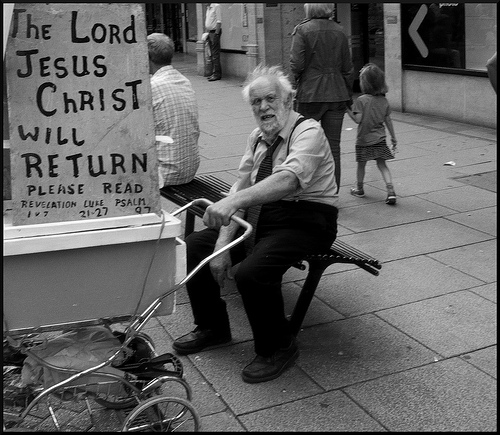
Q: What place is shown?
A: It is a sidewalk.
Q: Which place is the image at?
A: It is at the sidewalk.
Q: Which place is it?
A: It is a sidewalk.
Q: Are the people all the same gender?
A: No, they are both male and female.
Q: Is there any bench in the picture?
A: Yes, there is a bench.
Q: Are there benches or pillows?
A: Yes, there is a bench.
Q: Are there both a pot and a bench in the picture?
A: No, there is a bench but no pots.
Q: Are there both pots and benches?
A: No, there is a bench but no pots.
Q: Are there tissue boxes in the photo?
A: No, there are no tissue boxes.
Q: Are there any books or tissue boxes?
A: No, there are no tissue boxes or books.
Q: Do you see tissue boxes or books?
A: No, there are no tissue boxes or books.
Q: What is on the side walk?
A: The bench is on the side walk.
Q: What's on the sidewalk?
A: The bench is on the side walk.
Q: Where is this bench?
A: The bench is on the sidewalk.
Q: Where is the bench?
A: The bench is on the sidewalk.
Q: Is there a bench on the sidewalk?
A: Yes, there is a bench on the sidewalk.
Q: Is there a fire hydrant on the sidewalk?
A: No, there is a bench on the sidewalk.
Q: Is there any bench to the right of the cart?
A: Yes, there is a bench to the right of the cart.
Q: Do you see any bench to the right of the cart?
A: Yes, there is a bench to the right of the cart.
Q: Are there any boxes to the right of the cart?
A: No, there is a bench to the right of the cart.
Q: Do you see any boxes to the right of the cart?
A: No, there is a bench to the right of the cart.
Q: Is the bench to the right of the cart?
A: Yes, the bench is to the right of the cart.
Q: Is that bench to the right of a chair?
A: No, the bench is to the right of the cart.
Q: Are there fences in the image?
A: No, there are no fences.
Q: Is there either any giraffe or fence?
A: No, there are no fences or giraffes.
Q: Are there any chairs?
A: No, there are no chairs.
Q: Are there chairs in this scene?
A: No, there are no chairs.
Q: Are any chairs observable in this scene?
A: No, there are no chairs.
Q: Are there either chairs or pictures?
A: No, there are no chairs or pictures.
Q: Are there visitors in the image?
A: No, there are no visitors.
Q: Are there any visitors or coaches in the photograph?
A: No, there are no visitors or coaches.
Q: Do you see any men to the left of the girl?
A: Yes, there is a man to the left of the girl.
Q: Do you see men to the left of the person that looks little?
A: Yes, there is a man to the left of the girl.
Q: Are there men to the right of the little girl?
A: No, the man is to the left of the girl.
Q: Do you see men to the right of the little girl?
A: No, the man is to the left of the girl.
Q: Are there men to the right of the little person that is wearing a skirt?
A: No, the man is to the left of the girl.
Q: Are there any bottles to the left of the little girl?
A: No, there is a man to the left of the girl.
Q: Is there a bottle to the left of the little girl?
A: No, there is a man to the left of the girl.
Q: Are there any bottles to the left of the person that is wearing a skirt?
A: No, there is a man to the left of the girl.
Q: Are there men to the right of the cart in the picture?
A: Yes, there is a man to the right of the cart.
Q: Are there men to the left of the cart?
A: No, the man is to the right of the cart.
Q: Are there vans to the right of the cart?
A: No, there is a man to the right of the cart.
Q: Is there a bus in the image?
A: No, there are no buses.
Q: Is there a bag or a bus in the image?
A: No, there are no buses or bags.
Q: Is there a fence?
A: No, there are no fences.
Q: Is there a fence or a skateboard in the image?
A: No, there are no fences or skateboards.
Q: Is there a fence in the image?
A: No, there are no fences.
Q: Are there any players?
A: No, there are no players.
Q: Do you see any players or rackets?
A: No, there are no players or rackets.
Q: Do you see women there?
A: Yes, there is a woman.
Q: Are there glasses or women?
A: Yes, there is a woman.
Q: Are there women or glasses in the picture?
A: Yes, there is a woman.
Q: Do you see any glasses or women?
A: Yes, there is a woman.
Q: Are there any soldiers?
A: No, there are no soldiers.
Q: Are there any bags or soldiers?
A: No, there are no soldiers or bags.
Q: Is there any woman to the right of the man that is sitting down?
A: Yes, there is a woman to the right of the man.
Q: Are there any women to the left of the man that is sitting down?
A: No, the woman is to the right of the man.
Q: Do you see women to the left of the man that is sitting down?
A: No, the woman is to the right of the man.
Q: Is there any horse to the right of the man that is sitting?
A: No, there is a woman to the right of the man.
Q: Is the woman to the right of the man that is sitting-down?
A: Yes, the woman is to the right of the man.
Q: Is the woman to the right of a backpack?
A: No, the woman is to the right of the man.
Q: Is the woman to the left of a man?
A: No, the woman is to the right of a man.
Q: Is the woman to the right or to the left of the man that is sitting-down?
A: The woman is to the right of the man.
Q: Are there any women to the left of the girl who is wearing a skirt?
A: Yes, there is a woman to the left of the girl.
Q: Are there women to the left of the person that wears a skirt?
A: Yes, there is a woman to the left of the girl.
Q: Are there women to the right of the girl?
A: No, the woman is to the left of the girl.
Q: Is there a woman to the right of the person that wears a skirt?
A: No, the woman is to the left of the girl.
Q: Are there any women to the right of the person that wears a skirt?
A: No, the woman is to the left of the girl.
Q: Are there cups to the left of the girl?
A: No, there is a woman to the left of the girl.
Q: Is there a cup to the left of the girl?
A: No, there is a woman to the left of the girl.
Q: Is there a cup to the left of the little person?
A: No, there is a woman to the left of the girl.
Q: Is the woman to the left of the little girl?
A: Yes, the woman is to the left of the girl.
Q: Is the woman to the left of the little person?
A: Yes, the woman is to the left of the girl.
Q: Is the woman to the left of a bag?
A: No, the woman is to the left of the girl.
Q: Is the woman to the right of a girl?
A: No, the woman is to the left of a girl.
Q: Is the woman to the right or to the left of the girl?
A: The woman is to the left of the girl.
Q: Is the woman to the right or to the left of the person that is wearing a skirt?
A: The woman is to the left of the girl.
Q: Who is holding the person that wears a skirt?
A: The woman is holding the girl.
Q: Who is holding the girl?
A: The woman is holding the girl.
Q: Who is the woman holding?
A: The woman is holding the girl.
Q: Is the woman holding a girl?
A: Yes, the woman is holding a girl.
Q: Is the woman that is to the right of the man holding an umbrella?
A: No, the woman is holding a girl.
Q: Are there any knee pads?
A: No, there are no knee pads.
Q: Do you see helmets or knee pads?
A: No, there are no knee pads or helmets.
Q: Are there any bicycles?
A: No, there are no bicycles.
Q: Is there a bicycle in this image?
A: No, there are no bicycles.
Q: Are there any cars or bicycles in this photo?
A: No, there are no bicycles or cars.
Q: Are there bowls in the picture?
A: No, there are no bowls.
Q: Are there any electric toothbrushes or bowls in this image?
A: No, there are no bowls or electric toothbrushes.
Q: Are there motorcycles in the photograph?
A: No, there are no motorcycles.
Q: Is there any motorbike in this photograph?
A: No, there are no motorcycles.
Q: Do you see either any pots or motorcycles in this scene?
A: No, there are no motorcycles or pots.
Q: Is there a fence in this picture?
A: No, there are no fences.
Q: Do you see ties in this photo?
A: Yes, there is a tie.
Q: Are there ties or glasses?
A: Yes, there is a tie.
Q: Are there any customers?
A: No, there are no customers.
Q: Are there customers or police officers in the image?
A: No, there are no customers or police officers.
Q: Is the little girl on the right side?
A: Yes, the girl is on the right of the image.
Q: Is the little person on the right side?
A: Yes, the girl is on the right of the image.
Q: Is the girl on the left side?
A: No, the girl is on the right of the image.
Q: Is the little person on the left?
A: No, the girl is on the right of the image.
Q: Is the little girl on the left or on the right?
A: The girl is on the right of the image.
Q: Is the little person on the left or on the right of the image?
A: The girl is on the right of the image.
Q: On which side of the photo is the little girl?
A: The girl is on the right of the image.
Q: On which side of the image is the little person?
A: The girl is on the right of the image.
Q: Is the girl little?
A: Yes, the girl is little.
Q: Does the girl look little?
A: Yes, the girl is little.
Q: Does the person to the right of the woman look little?
A: Yes, the girl is little.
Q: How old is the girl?
A: The girl is little.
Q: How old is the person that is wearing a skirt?
A: The girl is little.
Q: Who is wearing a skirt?
A: The girl is wearing a skirt.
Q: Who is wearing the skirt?
A: The girl is wearing a skirt.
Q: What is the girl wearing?
A: The girl is wearing a skirt.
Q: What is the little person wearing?
A: The girl is wearing a skirt.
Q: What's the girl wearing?
A: The girl is wearing a skirt.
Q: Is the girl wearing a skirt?
A: Yes, the girl is wearing a skirt.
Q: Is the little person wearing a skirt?
A: Yes, the girl is wearing a skirt.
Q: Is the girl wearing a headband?
A: No, the girl is wearing a skirt.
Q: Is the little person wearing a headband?
A: No, the girl is wearing a skirt.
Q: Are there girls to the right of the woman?
A: Yes, there is a girl to the right of the woman.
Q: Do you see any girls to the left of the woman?
A: No, the girl is to the right of the woman.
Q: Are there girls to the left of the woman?
A: No, the girl is to the right of the woman.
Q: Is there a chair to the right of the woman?
A: No, there is a girl to the right of the woman.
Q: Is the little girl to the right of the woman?
A: Yes, the girl is to the right of the woman.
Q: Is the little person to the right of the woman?
A: Yes, the girl is to the right of the woman.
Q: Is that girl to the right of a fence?
A: No, the girl is to the right of the woman.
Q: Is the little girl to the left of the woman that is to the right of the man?
A: No, the girl is to the right of the woman.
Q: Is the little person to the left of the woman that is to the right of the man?
A: No, the girl is to the right of the woman.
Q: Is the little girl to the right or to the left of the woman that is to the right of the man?
A: The girl is to the right of the woman.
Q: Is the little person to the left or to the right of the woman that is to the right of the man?
A: The girl is to the right of the woman.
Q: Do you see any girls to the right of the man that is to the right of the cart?
A: Yes, there is a girl to the right of the man.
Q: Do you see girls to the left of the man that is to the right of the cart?
A: No, the girl is to the right of the man.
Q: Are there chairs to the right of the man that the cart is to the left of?
A: No, there is a girl to the right of the man.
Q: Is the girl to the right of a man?
A: Yes, the girl is to the right of a man.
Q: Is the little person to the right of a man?
A: Yes, the girl is to the right of a man.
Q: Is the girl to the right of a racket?
A: No, the girl is to the right of a man.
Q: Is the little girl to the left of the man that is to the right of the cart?
A: No, the girl is to the right of the man.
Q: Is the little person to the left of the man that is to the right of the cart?
A: No, the girl is to the right of the man.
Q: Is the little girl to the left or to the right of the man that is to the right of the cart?
A: The girl is to the right of the man.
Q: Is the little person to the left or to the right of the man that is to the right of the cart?
A: The girl is to the right of the man.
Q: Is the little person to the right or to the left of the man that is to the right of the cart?
A: The girl is to the right of the man.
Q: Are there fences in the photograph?
A: No, there are no fences.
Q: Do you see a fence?
A: No, there are no fences.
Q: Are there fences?
A: No, there are no fences.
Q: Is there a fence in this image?
A: No, there are no fences.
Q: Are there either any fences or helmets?
A: No, there are no fences or helmets.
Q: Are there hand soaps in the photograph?
A: No, there are no hand soaps.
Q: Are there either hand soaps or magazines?
A: No, there are no hand soaps or magazines.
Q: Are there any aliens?
A: No, there are no aliens.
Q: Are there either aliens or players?
A: No, there are no aliens or players.